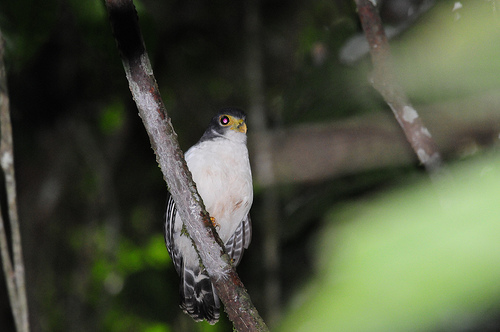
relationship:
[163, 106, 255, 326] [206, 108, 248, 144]
bird has head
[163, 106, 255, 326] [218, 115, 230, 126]
bird has eye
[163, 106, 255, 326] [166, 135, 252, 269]
bird has body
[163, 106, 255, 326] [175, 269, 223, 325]
bird has tail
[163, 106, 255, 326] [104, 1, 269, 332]
bird perched on branch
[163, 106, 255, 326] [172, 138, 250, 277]
bird has feathers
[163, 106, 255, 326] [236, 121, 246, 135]
bird has peck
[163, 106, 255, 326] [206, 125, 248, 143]
bird has neck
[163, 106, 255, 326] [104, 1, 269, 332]
bird on branch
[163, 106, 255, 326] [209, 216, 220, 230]
bird has claws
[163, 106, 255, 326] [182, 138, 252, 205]
bird has breast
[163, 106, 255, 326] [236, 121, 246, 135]
bird has beak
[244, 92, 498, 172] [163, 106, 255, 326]
branch behind bird